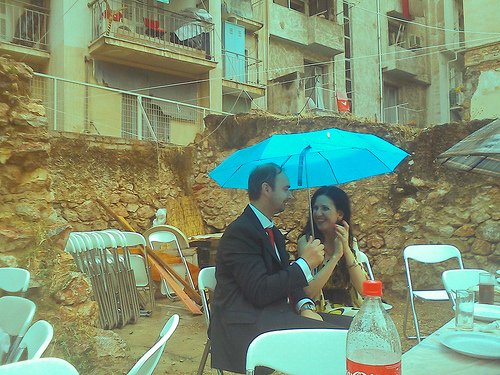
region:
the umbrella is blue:
[167, 110, 494, 264]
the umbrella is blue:
[202, 125, 353, 229]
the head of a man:
[243, 153, 298, 215]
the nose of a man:
[285, 189, 295, 202]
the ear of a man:
[258, 180, 271, 197]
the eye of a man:
[278, 184, 290, 196]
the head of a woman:
[306, 182, 354, 237]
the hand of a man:
[292, 233, 332, 277]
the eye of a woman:
[319, 200, 331, 212]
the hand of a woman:
[331, 216, 354, 251]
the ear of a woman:
[334, 204, 349, 222]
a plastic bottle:
[336, 271, 411, 373]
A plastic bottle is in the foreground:
[336, 273, 411, 374]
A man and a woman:
[202, 152, 390, 370]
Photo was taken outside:
[12, 6, 487, 371]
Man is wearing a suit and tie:
[201, 138, 298, 374]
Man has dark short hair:
[235, 156, 298, 220]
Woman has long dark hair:
[295, 173, 361, 259]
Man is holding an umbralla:
[205, 111, 422, 270]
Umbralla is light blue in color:
[203, 108, 414, 329]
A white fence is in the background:
[35, 70, 210, 150]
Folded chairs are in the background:
[66, 218, 161, 338]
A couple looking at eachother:
[191, 128, 391, 368]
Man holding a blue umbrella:
[199, 125, 379, 368]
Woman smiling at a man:
[301, 174, 371, 329]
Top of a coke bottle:
[336, 271, 418, 373]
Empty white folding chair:
[396, 239, 476, 341]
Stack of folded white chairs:
[57, 226, 168, 338]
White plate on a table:
[434, 322, 496, 365]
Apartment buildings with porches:
[0, 1, 457, 152]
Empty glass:
[450, 285, 484, 335]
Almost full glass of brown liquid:
[480, 265, 498, 316]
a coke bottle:
[336, 277, 410, 373]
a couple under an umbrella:
[203, 126, 413, 239]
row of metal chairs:
[65, 233, 196, 326]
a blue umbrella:
[201, 130, 426, 213]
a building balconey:
[87, 4, 229, 82]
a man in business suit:
[201, 194, 319, 347]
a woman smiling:
[301, 190, 372, 320]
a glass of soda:
[473, 270, 499, 316]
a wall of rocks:
[378, 182, 499, 303]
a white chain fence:
[58, 72, 190, 158]